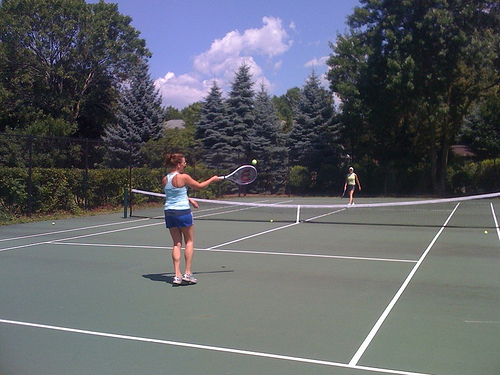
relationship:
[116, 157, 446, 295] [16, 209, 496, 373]
girls on court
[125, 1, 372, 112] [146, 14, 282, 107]
sky with clouds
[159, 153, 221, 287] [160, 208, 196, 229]
person wears shorts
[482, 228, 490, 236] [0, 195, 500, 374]
ball lies on court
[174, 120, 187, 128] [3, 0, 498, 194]
roof behind trees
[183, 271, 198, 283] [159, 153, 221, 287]
foot of person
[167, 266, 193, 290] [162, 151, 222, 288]
foot of person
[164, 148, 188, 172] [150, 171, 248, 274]
head of person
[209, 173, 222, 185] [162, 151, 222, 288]
hand of person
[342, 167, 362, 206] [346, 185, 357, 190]
person wearing shorts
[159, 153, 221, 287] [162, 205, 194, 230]
person wearing shorts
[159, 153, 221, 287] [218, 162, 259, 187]
person holding racket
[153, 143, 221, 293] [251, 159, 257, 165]
person hitting ball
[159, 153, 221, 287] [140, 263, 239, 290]
person casting shadow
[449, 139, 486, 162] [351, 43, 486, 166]
building in trees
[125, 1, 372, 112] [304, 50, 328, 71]
sky has part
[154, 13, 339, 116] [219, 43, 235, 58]
cloud has part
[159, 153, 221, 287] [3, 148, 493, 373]
person playing game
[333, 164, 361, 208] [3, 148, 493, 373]
person playing game